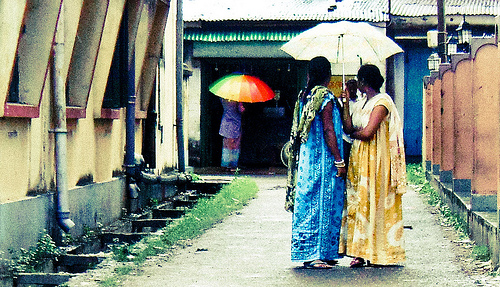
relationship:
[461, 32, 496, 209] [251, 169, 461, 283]
column by walkway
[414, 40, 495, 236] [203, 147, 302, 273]
column by walkway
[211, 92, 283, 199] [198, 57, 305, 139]
woman carrying umbrella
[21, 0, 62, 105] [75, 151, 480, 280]
column by walkway